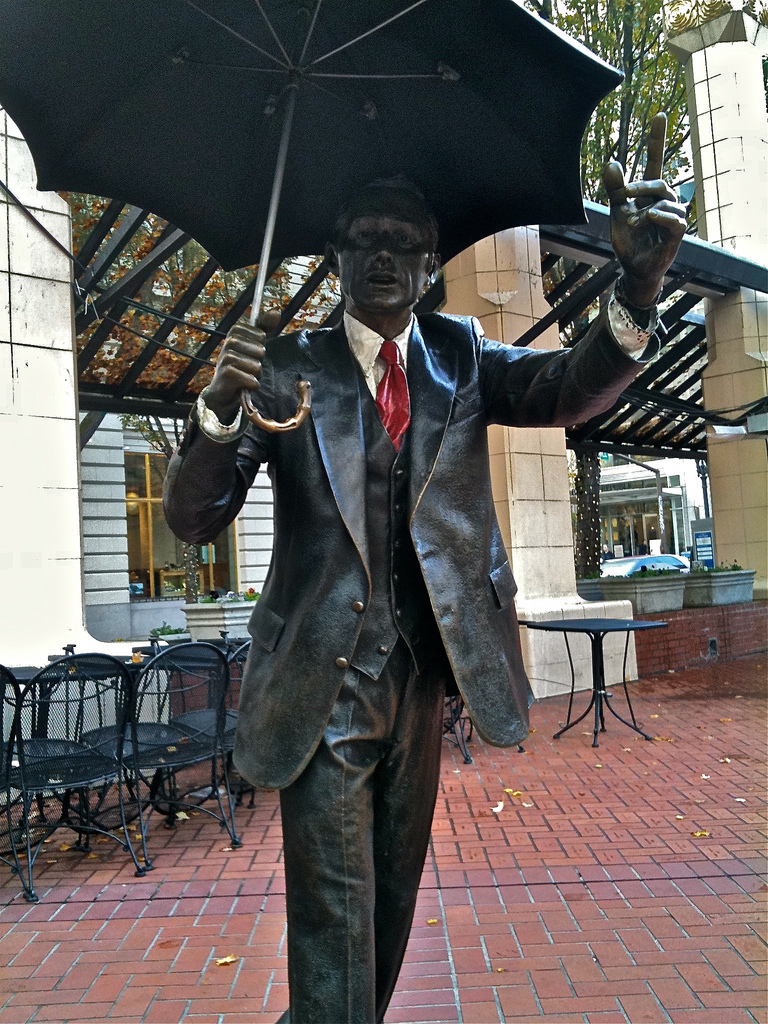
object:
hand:
[200, 317, 274, 404]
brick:
[531, 959, 581, 1005]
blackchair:
[110, 624, 257, 906]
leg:
[271, 638, 450, 1021]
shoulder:
[411, 302, 491, 389]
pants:
[270, 652, 448, 1022]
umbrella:
[2, 6, 619, 444]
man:
[164, 104, 694, 1018]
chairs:
[11, 651, 145, 894]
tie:
[372, 334, 416, 455]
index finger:
[642, 109, 672, 181]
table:
[518, 610, 679, 749]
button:
[350, 600, 364, 614]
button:
[334, 654, 349, 671]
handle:
[240, 83, 319, 444]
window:
[121, 447, 241, 606]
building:
[2, 5, 641, 782]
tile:
[3, 132, 76, 217]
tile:
[0, 205, 77, 288]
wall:
[4, 113, 89, 795]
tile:
[5, 265, 76, 358]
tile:
[0, 336, 84, 426]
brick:
[491, 860, 523, 888]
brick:
[183, 868, 223, 895]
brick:
[79, 890, 121, 923]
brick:
[643, 789, 671, 816]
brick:
[66, 871, 108, 906]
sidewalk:
[5, 663, 765, 1021]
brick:
[572, 972, 653, 997]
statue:
[2, 3, 710, 1019]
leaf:
[212, 950, 239, 969]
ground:
[9, 624, 763, 1018]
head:
[323, 161, 441, 317]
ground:
[417, 640, 767, 1023]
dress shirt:
[161, 296, 654, 1021]